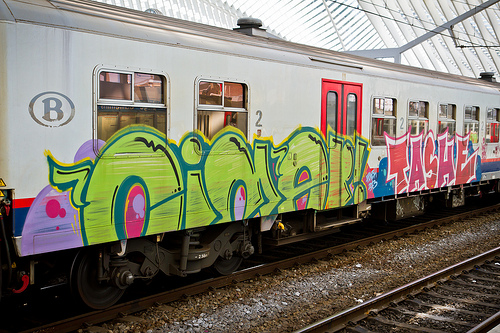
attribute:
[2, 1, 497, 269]
train — red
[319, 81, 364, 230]
doors — red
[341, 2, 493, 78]
wires — metal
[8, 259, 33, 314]
machinery — big, red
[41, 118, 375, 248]
caligraphy — green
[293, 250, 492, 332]
rail track — metal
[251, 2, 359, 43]
light — sun 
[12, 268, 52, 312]
machinery — red, big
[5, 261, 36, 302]
machinery — big